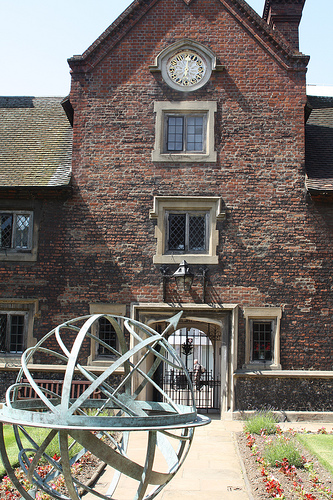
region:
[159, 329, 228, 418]
A decorative iron gate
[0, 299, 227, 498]
A spherical metallic sculpture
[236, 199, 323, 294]
Red brick that is centuries old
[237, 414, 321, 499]
Area of a flower garden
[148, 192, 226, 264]
A lead window with concrede frame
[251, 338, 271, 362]
A vase with red flowers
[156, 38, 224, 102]
Clock on the building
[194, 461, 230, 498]
Sidewalk between the flower beds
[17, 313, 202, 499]
Round sculpture on sidewalk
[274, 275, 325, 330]
Wall made of brick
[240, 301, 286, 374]
Window on the building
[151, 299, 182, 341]
Arrow on the sculpture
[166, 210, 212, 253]
Mesh on the window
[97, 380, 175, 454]
Sculpture is made of metal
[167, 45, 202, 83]
white clock on building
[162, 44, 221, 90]
clock has grey frame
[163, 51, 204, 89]
clock has white face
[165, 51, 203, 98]
clock has gold numbers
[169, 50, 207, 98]
clock has white hands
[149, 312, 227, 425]
black gate on door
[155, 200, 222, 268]
grey frame on window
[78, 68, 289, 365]
building is dark red brick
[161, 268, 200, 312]
black light above door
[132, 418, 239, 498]
light brown concrete leading to door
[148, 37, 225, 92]
clock on front of building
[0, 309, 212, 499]
large metal sculpture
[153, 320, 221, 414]
an iron gate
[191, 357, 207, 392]
man standing inside coutyard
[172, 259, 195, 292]
light fixture above entrance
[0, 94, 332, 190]
shingled roof top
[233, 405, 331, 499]
row of flowers and plants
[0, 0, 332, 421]
large brick building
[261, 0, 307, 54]
brick chimney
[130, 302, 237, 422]
decorative doorway trim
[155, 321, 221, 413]
Black gate on a doorway.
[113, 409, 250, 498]
Red walkway leading to a black gated archway.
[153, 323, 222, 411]
The metal gate in the entreway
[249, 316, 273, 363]
The window beside the entreway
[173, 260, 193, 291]
The light over the entreway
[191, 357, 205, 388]
The person behind the gate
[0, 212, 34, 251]
The window under the roof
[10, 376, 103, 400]
The bench behind the sculpture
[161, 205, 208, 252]
The window above the lamp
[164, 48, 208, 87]
The clock on the building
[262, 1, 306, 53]
The chimney on the roof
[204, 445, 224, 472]
the ground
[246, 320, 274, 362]
a window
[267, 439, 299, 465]
small batch of grass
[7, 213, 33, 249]
a window on the building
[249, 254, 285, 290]
bricks are brown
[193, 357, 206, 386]
a person standing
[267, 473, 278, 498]
small flowers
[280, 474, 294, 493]
the dirt is brown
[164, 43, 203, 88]
clock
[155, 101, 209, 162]
window in brick building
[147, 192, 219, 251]
window in brick building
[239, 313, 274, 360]
window in brick building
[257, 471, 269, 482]
red flowers in ground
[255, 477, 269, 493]
red flowers in ground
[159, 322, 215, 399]
arched entrance to building